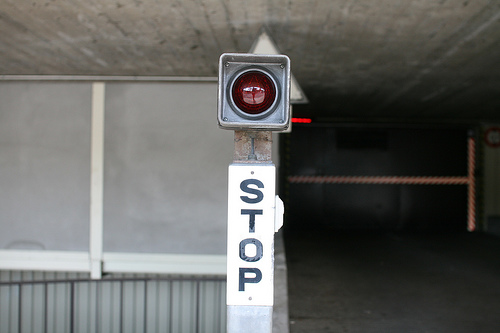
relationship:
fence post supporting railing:
[68, 282, 77, 331] [1, 269, 227, 331]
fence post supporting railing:
[15, 281, 22, 331] [1, 269, 227, 331]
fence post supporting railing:
[42, 281, 49, 331] [1, 269, 227, 331]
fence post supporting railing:
[117, 277, 125, 329] [1, 269, 227, 331]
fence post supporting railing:
[166, 276, 175, 331] [1, 269, 227, 331]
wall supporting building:
[1, 78, 233, 331] [2, 0, 484, 329]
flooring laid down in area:
[284, 213, 483, 330] [280, 92, 484, 329]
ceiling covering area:
[2, 1, 484, 123] [2, 2, 483, 329]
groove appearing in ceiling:
[8, 0, 110, 73] [2, 1, 484, 123]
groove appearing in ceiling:
[87, 0, 162, 74] [2, 1, 484, 123]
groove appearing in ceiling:
[176, 0, 216, 74] [2, 1, 484, 123]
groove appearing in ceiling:
[221, 0, 240, 56] [2, 1, 484, 123]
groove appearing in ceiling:
[141, 15, 197, 76] [2, 1, 484, 123]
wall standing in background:
[281, 121, 483, 219] [281, 101, 484, 233]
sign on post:
[230, 168, 275, 310] [231, 132, 276, 328]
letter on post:
[239, 178, 262, 294] [210, 136, 291, 330]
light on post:
[217, 51, 289, 130] [218, 131, 280, 331]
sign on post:
[225, 165, 275, 306] [212, 139, 281, 323]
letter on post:
[239, 178, 262, 294] [224, 134, 287, 330]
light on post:
[217, 51, 289, 130] [217, 137, 285, 331]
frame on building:
[16, 246, 173, 288] [42, 133, 152, 232]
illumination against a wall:
[292, 118, 311, 123] [279, 114, 479, 236]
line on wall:
[87, 75, 107, 279] [0, 77, 292, 331]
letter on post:
[239, 178, 262, 294] [222, 160, 274, 330]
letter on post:
[239, 209, 263, 229] [222, 160, 274, 330]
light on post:
[217, 51, 289, 130] [217, 51, 291, 330]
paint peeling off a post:
[270, 192, 285, 234] [217, 51, 291, 330]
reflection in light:
[237, 86, 267, 106] [217, 51, 289, 130]